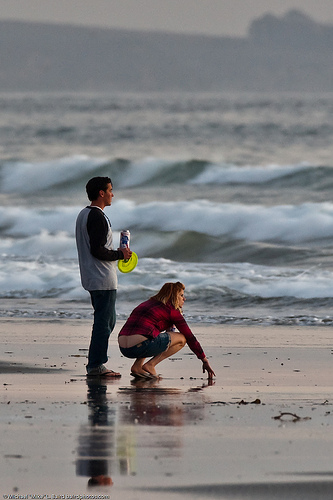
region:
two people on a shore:
[0, 175, 331, 405]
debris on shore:
[206, 393, 331, 435]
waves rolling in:
[0, 143, 332, 323]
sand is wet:
[0, 325, 331, 492]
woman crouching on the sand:
[117, 280, 218, 384]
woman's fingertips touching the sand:
[192, 349, 217, 385]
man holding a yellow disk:
[117, 247, 138, 273]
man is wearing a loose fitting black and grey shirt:
[74, 204, 124, 291]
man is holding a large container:
[119, 227, 131, 259]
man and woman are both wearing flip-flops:
[84, 354, 164, 382]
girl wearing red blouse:
[115, 303, 208, 331]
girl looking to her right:
[126, 279, 212, 397]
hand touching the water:
[196, 352, 231, 393]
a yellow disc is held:
[111, 252, 138, 272]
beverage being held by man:
[115, 224, 129, 247]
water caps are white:
[131, 201, 323, 240]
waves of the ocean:
[124, 161, 331, 197]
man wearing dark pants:
[84, 288, 119, 361]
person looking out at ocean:
[84, 168, 121, 411]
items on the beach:
[210, 390, 307, 432]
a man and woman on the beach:
[64, 163, 241, 412]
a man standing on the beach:
[65, 171, 142, 400]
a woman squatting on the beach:
[114, 271, 231, 394]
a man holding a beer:
[117, 220, 143, 280]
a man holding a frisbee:
[110, 240, 138, 285]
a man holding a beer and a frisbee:
[101, 210, 146, 279]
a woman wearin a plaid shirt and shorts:
[102, 284, 221, 412]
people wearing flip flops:
[78, 357, 175, 392]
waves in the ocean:
[134, 153, 308, 280]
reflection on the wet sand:
[62, 381, 215, 499]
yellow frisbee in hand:
[120, 251, 137, 271]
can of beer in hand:
[120, 228, 130, 247]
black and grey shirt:
[74, 207, 122, 290]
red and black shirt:
[121, 296, 206, 360]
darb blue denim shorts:
[123, 334, 171, 356]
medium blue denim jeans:
[87, 289, 117, 367]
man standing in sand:
[72, 173, 137, 377]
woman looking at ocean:
[119, 281, 216, 383]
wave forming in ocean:
[1, 123, 331, 142]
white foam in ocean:
[2, 261, 332, 293]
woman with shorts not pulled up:
[117, 282, 215, 381]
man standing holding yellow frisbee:
[75, 174, 138, 379]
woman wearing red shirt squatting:
[118, 282, 215, 383]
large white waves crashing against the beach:
[234, 201, 320, 240]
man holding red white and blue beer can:
[119, 229, 131, 251]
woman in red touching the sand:
[117, 280, 216, 386]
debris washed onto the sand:
[274, 411, 308, 421]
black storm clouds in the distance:
[247, 10, 315, 46]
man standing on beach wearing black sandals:
[75, 175, 131, 379]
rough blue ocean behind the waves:
[224, 99, 286, 135]